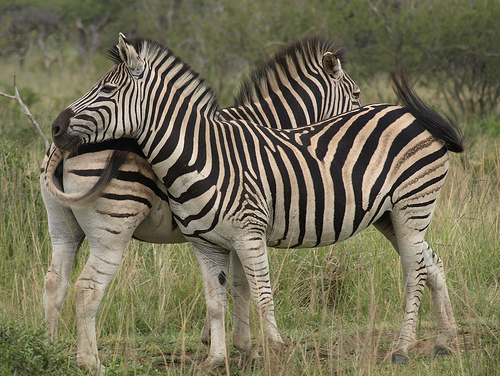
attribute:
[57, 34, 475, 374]
zebra — standing outside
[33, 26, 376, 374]
zebra — standing outside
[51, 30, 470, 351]
zebra — standing outside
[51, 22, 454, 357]
fur — striped, white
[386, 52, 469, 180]
tail — black, swishing, flicked up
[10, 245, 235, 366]
leg fur — white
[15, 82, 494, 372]
grass — tall, yellow, grassy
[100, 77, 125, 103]
eye — black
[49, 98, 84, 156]
front of face — black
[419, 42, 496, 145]
bush — brown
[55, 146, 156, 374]
leg — thick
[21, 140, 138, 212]
tail — brown, curved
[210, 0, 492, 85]
plant — green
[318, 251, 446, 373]
plant — brown